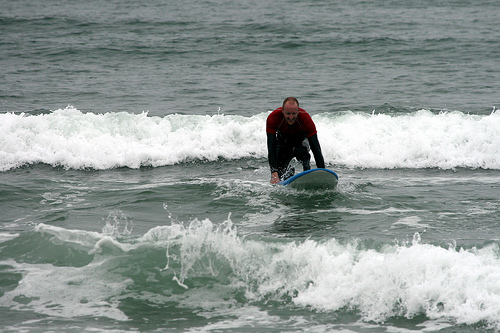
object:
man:
[265, 96, 325, 186]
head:
[279, 97, 302, 125]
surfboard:
[280, 167, 341, 187]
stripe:
[283, 167, 318, 181]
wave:
[0, 107, 500, 177]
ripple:
[116, 24, 188, 37]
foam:
[3, 257, 137, 327]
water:
[1, 1, 500, 332]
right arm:
[265, 113, 286, 189]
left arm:
[301, 111, 326, 170]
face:
[283, 106, 300, 125]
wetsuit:
[263, 107, 325, 173]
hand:
[267, 172, 282, 185]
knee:
[296, 144, 312, 163]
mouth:
[285, 116, 296, 123]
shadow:
[276, 189, 338, 237]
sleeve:
[307, 120, 328, 169]